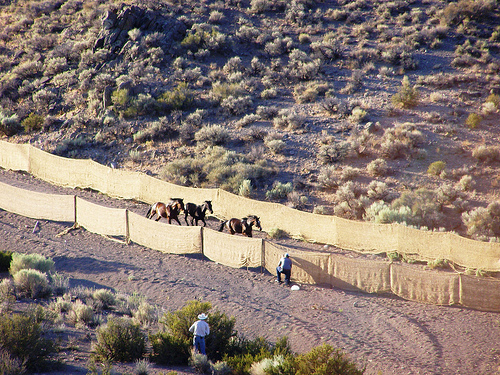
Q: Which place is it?
A: It is a road.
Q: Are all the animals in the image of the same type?
A: Yes, all the animals are horses.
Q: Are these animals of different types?
A: No, all the animals are horses.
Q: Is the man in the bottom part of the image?
A: Yes, the man is in the bottom of the image.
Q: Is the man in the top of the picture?
A: No, the man is in the bottom of the image.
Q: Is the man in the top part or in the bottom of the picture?
A: The man is in the bottom of the image.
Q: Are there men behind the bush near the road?
A: Yes, there is a man behind the shrub.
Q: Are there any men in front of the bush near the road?
A: No, the man is behind the bush.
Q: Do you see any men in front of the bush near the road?
A: No, the man is behind the bush.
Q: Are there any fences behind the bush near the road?
A: No, there is a man behind the bush.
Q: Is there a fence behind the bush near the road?
A: No, there is a man behind the bush.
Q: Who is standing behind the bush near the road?
A: The man is standing behind the shrub.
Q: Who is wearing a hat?
A: The man is wearing a hat.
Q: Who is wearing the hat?
A: The man is wearing a hat.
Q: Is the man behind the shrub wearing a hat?
A: Yes, the man is wearing a hat.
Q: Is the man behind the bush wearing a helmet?
A: No, the man is wearing a hat.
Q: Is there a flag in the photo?
A: No, there are no flags.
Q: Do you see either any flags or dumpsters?
A: No, there are no flags or dumpsters.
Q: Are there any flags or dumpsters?
A: No, there are no flags or dumpsters.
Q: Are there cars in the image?
A: No, there are no cars.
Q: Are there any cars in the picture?
A: No, there are no cars.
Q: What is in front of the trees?
A: The road is in front of the trees.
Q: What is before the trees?
A: The road is in front of the trees.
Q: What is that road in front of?
A: The road is in front of the trees.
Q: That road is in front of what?
A: The road is in front of the trees.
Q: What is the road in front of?
A: The road is in front of the trees.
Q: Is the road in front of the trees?
A: Yes, the road is in front of the trees.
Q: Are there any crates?
A: No, there are no crates.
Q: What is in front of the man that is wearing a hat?
A: The shrub is in front of the man.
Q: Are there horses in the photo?
A: Yes, there is a horse.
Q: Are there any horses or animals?
A: Yes, there is a horse.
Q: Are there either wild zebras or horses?
A: Yes, there is a wild horse.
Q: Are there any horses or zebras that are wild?
A: Yes, the horse is wild.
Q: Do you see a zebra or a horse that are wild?
A: Yes, the horse is wild.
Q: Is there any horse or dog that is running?
A: Yes, the horse is running.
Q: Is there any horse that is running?
A: Yes, there is a horse that is running.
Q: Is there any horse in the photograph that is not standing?
A: Yes, there is a horse that is running.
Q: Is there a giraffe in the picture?
A: No, there are no giraffes.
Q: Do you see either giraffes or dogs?
A: No, there are no giraffes or dogs.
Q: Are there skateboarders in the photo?
A: No, there are no skateboarders.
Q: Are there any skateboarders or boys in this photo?
A: No, there are no skateboarders or boys.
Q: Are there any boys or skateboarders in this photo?
A: No, there are no skateboarders or boys.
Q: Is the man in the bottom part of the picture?
A: Yes, the man is in the bottom of the image.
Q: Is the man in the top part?
A: No, the man is in the bottom of the image.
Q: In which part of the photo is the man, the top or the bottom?
A: The man is in the bottom of the image.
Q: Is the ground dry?
A: Yes, the ground is dry.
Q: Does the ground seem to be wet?
A: No, the ground is dry.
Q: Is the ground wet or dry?
A: The ground is dry.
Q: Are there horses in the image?
A: Yes, there is a horse.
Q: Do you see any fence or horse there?
A: Yes, there is a horse.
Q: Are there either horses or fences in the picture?
A: Yes, there is a horse.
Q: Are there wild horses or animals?
A: Yes, there is a wild horse.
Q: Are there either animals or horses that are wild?
A: Yes, the horse is wild.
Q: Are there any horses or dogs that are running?
A: Yes, the horse is running.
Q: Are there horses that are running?
A: Yes, there is a horse that is running.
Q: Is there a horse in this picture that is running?
A: Yes, there is a horse that is running.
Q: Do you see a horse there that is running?
A: Yes, there is a horse that is running.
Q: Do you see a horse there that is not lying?
A: Yes, there is a horse that is running .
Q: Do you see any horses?
A: Yes, there is a horse.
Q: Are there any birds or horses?
A: Yes, there is a horse.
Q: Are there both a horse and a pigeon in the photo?
A: No, there is a horse but no pigeons.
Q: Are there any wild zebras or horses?
A: Yes, there is a wild horse.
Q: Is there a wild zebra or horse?
A: Yes, there is a wild horse.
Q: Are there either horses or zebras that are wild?
A: Yes, the horse is wild.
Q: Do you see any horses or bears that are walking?
A: Yes, the horse is walking.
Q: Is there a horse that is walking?
A: Yes, there is a horse that is walking.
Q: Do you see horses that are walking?
A: Yes, there is a horse that is walking.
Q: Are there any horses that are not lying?
A: Yes, there is a horse that is walking.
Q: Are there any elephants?
A: No, there are no elephants.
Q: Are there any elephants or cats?
A: No, there are no elephants or cats.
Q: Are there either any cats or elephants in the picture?
A: No, there are no elephants or cats.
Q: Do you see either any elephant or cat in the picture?
A: No, there are no elephants or cats.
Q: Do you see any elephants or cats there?
A: No, there are no elephants or cats.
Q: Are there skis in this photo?
A: No, there are no skis.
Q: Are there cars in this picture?
A: No, there are no cars.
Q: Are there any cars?
A: No, there are no cars.